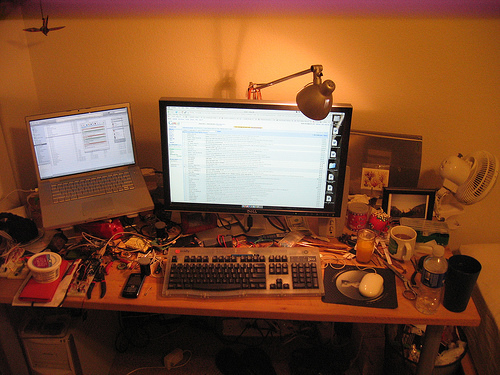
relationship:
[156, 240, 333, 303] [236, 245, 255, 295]
keyboard with keys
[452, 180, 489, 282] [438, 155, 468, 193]
back side of a fan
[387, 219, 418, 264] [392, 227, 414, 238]
white mug full of coffee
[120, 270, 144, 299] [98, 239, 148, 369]
cell phone a bar style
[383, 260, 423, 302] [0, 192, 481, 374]
scissors laid on a desk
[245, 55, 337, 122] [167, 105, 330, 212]
lamp hangs over monitor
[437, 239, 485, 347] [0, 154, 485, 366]
cup on edge of desk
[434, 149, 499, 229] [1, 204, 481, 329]
fan on desk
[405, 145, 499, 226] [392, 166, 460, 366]
fan on edge of desk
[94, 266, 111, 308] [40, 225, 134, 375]
pliers are on desk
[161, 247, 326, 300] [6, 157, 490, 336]
keyboard on desk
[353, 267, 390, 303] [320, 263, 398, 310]
mouse on mouse mousepad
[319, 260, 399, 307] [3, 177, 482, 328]
mousepad on desk